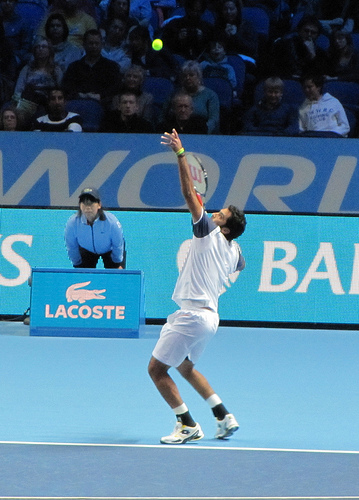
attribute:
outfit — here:
[144, 224, 250, 376]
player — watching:
[154, 122, 255, 436]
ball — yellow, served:
[150, 34, 167, 55]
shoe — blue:
[165, 421, 205, 442]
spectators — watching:
[2, 4, 355, 135]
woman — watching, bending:
[63, 184, 129, 271]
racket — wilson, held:
[180, 147, 214, 214]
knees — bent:
[142, 347, 212, 384]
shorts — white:
[136, 304, 220, 370]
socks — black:
[172, 400, 227, 429]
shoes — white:
[150, 413, 245, 452]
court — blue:
[5, 316, 358, 485]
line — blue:
[5, 429, 355, 483]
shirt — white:
[175, 200, 248, 312]